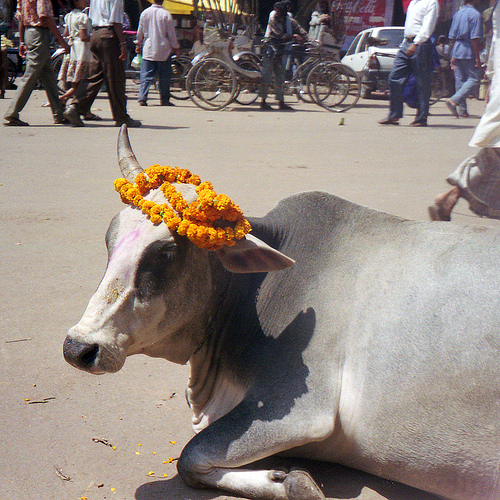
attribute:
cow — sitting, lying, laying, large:
[67, 137, 491, 496]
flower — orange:
[136, 181, 223, 257]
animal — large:
[57, 162, 488, 468]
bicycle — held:
[189, 48, 375, 122]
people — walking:
[41, 4, 475, 146]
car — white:
[348, 12, 435, 121]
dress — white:
[67, 23, 90, 63]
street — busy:
[39, 103, 449, 202]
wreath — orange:
[63, 170, 290, 295]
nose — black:
[53, 300, 125, 413]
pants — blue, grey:
[379, 38, 478, 139]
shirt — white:
[388, 4, 479, 69]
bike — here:
[206, 56, 393, 114]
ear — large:
[224, 227, 311, 285]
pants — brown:
[81, 17, 126, 107]